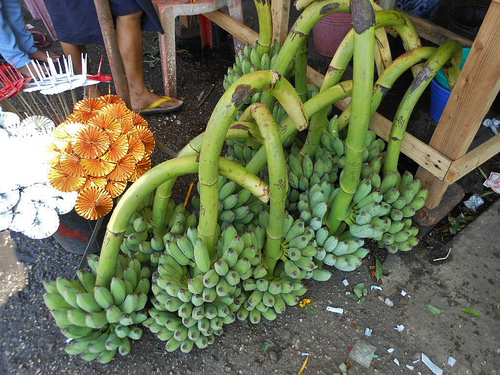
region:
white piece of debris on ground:
[316, 300, 359, 321]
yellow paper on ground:
[295, 290, 312, 313]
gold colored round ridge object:
[62, 125, 114, 155]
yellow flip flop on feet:
[133, 94, 195, 122]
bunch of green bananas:
[63, 290, 143, 349]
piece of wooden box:
[436, 101, 498, 158]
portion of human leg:
[102, 34, 158, 89]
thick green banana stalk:
[113, 171, 283, 227]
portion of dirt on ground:
[448, 213, 463, 236]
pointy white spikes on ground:
[22, 47, 114, 89]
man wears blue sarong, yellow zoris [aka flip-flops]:
[38, 0, 168, 49]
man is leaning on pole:
[91, 0, 134, 113]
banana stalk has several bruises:
[283, 0, 377, 41]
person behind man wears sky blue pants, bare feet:
[0, 0, 64, 82]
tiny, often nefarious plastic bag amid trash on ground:
[346, 335, 378, 370]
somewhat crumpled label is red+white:
[480, 167, 499, 193]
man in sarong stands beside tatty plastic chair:
[147, 0, 247, 99]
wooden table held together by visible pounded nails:
[404, 139, 471, 209]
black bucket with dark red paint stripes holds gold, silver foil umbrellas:
[44, 205, 116, 261]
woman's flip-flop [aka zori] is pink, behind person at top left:
[26, 28, 53, 50]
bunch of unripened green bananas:
[46, 249, 145, 361]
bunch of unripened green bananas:
[121, 193, 187, 253]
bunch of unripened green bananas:
[148, 227, 253, 349]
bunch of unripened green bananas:
[241, 210, 313, 317]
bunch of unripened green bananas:
[298, 179, 382, 279]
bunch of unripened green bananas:
[225, 46, 288, 118]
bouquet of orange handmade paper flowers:
[53, 101, 152, 213]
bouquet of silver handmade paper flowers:
[0, 114, 75, 236]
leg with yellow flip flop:
[118, 8, 182, 114]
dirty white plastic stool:
[149, 0, 232, 102]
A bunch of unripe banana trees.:
[41, 3, 460, 373]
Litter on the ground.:
[325, 280, 470, 373]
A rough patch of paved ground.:
[0, 308, 47, 373]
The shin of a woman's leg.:
[116, 14, 184, 117]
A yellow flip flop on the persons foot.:
[140, 97, 185, 111]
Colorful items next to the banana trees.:
[0, 52, 155, 249]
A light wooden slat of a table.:
[436, 0, 498, 193]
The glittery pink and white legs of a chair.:
[162, 2, 241, 98]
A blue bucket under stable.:
[435, 78, 488, 133]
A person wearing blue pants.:
[1, 0, 83, 65]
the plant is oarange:
[63, 121, 141, 177]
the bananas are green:
[161, 253, 290, 308]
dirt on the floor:
[331, 270, 441, 360]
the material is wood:
[426, 131, 472, 195]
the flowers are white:
[8, 132, 70, 236]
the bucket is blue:
[431, 82, 440, 119]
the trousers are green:
[0, 11, 31, 51]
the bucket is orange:
[318, 27, 338, 62]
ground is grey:
[323, 301, 478, 371]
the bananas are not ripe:
[161, 265, 304, 323]